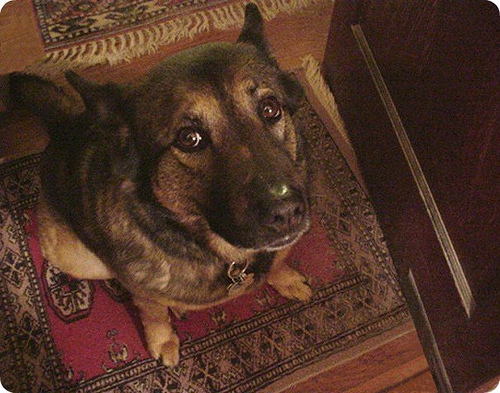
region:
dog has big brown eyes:
[161, 86, 301, 136]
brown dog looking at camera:
[98, 35, 330, 242]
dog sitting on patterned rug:
[28, 71, 388, 351]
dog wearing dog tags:
[206, 242, 256, 292]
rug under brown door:
[362, 155, 452, 336]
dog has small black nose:
[252, 183, 318, 229]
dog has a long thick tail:
[10, 65, 91, 145]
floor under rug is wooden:
[342, 346, 427, 382]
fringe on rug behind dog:
[70, 5, 240, 65]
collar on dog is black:
[171, 212, 273, 307]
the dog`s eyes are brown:
[166, 87, 301, 158]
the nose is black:
[227, 167, 329, 263]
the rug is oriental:
[3, 199, 370, 371]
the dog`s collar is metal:
[178, 242, 283, 317]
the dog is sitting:
[6, 54, 336, 362]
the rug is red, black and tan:
[2, 230, 364, 352]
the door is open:
[310, 2, 497, 382]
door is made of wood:
[320, 5, 497, 355]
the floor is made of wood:
[2, 0, 313, 101]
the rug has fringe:
[18, 2, 300, 79]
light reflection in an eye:
[255, 97, 279, 117]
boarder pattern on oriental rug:
[5, 300, 59, 391]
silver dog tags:
[218, 259, 258, 301]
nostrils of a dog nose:
[263, 202, 310, 231]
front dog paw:
[141, 322, 186, 369]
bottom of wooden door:
[319, 22, 490, 391]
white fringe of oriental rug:
[51, 15, 233, 42]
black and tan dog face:
[134, 61, 317, 262]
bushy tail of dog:
[6, 67, 72, 135]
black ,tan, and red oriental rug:
[5, 140, 400, 391]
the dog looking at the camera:
[19, 44, 340, 346]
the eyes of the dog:
[137, 86, 327, 168]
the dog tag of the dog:
[206, 249, 281, 306]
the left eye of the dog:
[153, 113, 219, 173]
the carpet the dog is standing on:
[59, 296, 134, 359]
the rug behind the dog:
[46, 28, 201, 72]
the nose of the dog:
[246, 171, 331, 253]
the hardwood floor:
[369, 356, 396, 377]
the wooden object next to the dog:
[369, 35, 471, 214]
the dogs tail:
[25, 60, 47, 140]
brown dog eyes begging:
[162, 91, 307, 167]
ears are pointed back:
[48, 0, 308, 107]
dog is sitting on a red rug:
[3, 43, 451, 389]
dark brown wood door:
[318, 1, 498, 388]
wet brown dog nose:
[253, 188, 308, 246]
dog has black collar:
[207, 246, 283, 291]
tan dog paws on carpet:
[130, 279, 323, 379]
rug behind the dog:
[37, 5, 309, 54]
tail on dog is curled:
[12, 72, 114, 199]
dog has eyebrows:
[162, 72, 274, 142]